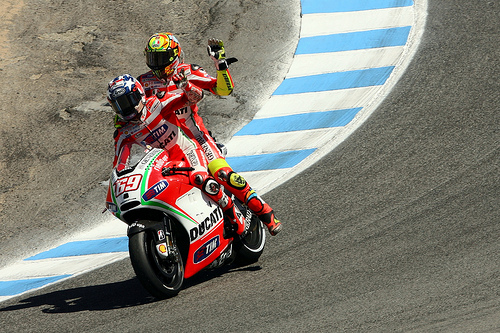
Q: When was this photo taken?
A: During the day.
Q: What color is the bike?
A: Red.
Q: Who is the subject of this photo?
A: The bikers.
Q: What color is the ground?
A: Gray.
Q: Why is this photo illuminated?
A: Sunlight.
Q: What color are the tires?
A: Black.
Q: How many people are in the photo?
A: 2.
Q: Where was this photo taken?
A: On a motorcycle track.